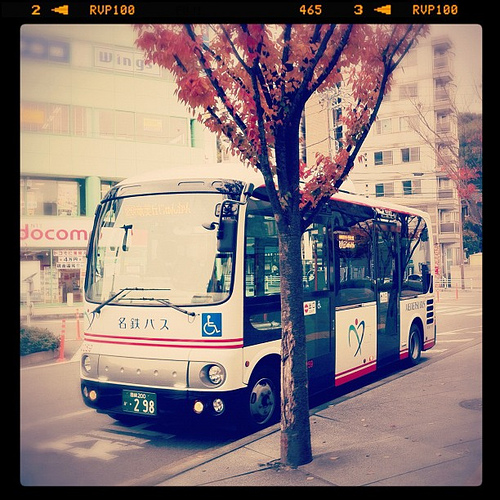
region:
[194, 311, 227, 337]
HANDICAP SIGN ON BUS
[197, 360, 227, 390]
FRONT HEADLIGHT FOR BUS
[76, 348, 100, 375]
FRONT HEADLIGHT FOR BUS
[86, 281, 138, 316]
WINDSHIELD WIPER FOR BUS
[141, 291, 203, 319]
WINDSHIELD WIPER FOR BUS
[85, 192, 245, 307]
FRONT WINDSHIELD OF BUS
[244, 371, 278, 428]
FRONT WHEEL OF BUS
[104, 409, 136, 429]
FRONT WHEEL OF BUS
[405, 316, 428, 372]
REAR WHEEL OF BUS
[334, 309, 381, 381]
ADVERTISING SIGN ON SIDE OF BUS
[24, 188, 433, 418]
the bus is white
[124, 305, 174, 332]
the text is blue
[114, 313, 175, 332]
the text is japanese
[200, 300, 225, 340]
the sign is blue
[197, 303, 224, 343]
this is for the handicapped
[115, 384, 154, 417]
the number is 298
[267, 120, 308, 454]
tree next to the bus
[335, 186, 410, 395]
the bus is open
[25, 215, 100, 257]
the text is red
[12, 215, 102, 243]
the sign is white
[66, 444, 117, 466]
Part of the street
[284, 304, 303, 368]
Part of the tree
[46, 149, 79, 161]
Part of the building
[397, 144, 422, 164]
A window on the building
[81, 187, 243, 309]
A window on the bus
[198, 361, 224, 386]
The left headlight of the bus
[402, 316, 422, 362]
The back tire of the bus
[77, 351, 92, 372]
The right headlight of the bus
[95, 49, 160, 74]
Letters on the building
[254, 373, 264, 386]
Part of the front tire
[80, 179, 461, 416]
a bus on the road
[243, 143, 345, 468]
a tree on the sidewalk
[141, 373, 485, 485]
the sidewalk next to the bus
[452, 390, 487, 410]
a storm drain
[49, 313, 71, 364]
yellow traffic cones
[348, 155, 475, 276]
a building behind the bus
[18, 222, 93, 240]
a sign on the building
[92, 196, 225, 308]
the windshield on the bus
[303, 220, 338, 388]
doors on the bus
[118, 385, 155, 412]
the license plate on the bus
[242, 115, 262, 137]
the leaf is red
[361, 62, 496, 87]
the leaf is orange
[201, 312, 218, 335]
the sign is blue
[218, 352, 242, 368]
the bus is white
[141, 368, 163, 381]
the bus is gray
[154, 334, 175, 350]
the lines are red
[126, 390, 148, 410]
the tag is green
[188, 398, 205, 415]
the light is on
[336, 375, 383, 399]
it's parked by the curb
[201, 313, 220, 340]
the sign has a wheelchair on it